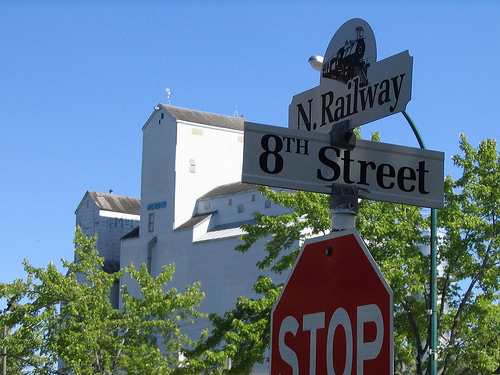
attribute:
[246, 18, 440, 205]
signs — white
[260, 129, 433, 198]
letters — black, white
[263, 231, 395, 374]
sign — white, octagon, written, red, black, painted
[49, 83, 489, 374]
building — white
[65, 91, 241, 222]
roof — Black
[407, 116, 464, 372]
pole — green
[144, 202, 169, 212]
label — blue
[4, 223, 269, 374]
trees — behind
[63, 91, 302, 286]
factory — white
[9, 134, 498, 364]
tree — green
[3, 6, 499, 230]
sky — blue